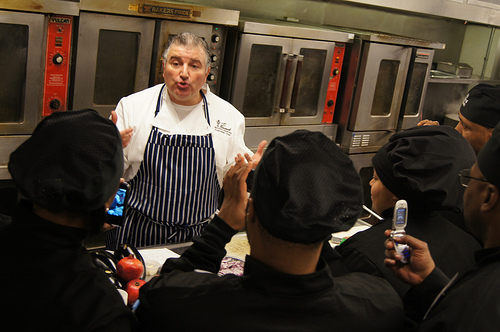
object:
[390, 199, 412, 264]
flip phone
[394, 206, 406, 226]
picture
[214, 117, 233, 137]
black writing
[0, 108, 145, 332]
man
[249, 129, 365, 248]
black hat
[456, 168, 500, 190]
glasses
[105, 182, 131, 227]
phone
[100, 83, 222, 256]
apron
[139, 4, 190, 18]
sign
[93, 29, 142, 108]
window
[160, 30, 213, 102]
head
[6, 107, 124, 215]
hat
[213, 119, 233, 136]
logo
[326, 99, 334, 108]
knobs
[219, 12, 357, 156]
oven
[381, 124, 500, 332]
man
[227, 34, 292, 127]
doors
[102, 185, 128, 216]
screen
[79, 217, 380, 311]
counter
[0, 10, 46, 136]
oven door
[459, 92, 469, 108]
writing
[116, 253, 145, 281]
apple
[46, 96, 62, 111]
knobs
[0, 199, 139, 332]
shirt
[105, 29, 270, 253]
man